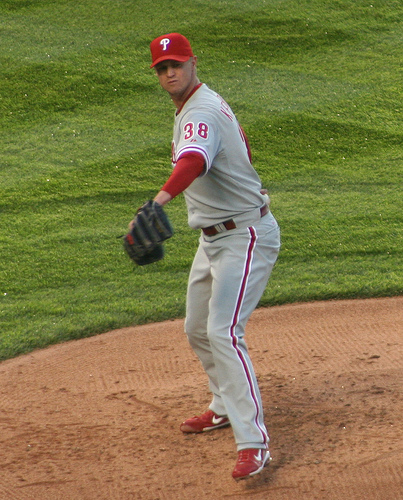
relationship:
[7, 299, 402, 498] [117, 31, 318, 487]
mound for pitcher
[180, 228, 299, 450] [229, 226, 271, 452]
pants with stripe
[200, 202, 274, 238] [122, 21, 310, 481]
belt of man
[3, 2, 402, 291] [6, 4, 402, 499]
grass in field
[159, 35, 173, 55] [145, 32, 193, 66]
logo on cap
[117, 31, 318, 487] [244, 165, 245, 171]
player has gray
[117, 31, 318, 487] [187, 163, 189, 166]
player has red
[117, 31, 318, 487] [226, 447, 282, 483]
he has shoe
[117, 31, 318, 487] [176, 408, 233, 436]
he has shoe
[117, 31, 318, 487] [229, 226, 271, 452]
he has stripe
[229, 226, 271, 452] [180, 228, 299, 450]
stripe on pants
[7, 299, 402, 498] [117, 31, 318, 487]
mound of pitcher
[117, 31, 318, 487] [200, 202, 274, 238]
he wearing belt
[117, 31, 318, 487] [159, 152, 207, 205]
he has shirt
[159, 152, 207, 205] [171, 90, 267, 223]
shirt under jersey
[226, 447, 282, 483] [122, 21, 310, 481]
shoe of man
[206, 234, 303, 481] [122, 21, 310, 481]
leg of man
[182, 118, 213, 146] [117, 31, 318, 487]
number of player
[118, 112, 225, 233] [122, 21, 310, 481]
arm of man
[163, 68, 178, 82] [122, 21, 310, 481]
nose of man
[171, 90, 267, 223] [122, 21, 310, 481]
jersey of man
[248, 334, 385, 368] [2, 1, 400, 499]
track in photo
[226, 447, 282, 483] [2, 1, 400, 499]
shoe in photo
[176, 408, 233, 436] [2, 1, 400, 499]
shoe in photo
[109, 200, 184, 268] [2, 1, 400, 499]
glove in photo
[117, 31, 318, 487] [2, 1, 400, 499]
player in photo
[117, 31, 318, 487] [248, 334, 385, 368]
player on track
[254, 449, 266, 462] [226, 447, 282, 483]
logo on shoe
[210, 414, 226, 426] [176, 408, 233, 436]
logo on shoe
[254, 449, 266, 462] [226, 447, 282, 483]
stripe on shoe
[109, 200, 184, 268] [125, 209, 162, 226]
glove in hand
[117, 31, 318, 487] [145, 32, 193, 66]
he wearing cap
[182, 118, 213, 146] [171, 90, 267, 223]
number on shirt